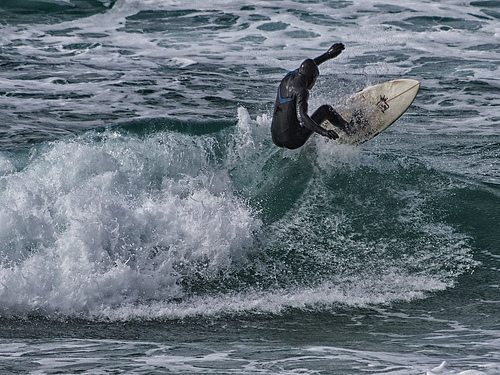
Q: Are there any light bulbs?
A: No, there are no light bulbs.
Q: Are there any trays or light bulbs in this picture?
A: No, there are no light bulbs or trays.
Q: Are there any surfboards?
A: Yes, there is a surfboard.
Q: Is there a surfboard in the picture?
A: Yes, there is a surfboard.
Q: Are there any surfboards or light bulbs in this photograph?
A: Yes, there is a surfboard.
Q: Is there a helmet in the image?
A: No, there are no helmets.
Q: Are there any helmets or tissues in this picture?
A: No, there are no helmets or tissues.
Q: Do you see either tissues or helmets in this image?
A: No, there are no helmets or tissues.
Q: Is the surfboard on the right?
A: Yes, the surfboard is on the right of the image.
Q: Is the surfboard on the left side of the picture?
A: No, the surfboard is on the right of the image.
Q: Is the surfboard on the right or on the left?
A: The surfboard is on the right of the image.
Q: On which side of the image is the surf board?
A: The surf board is on the right of the image.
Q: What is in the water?
A: The surfboard is in the water.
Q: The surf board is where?
A: The surf board is in the water.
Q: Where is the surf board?
A: The surf board is in the water.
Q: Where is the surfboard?
A: The surf board is in the water.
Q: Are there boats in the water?
A: No, there is a surfboard in the water.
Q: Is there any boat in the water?
A: No, there is a surfboard in the water.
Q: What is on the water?
A: The surf board is on the water.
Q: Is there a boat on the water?
A: No, there is a surfboard on the water.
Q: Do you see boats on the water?
A: No, there is a surfboard on the water.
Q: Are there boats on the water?
A: No, there is a surfboard on the water.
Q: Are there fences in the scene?
A: No, there are no fences.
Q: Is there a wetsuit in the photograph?
A: Yes, there is a wetsuit.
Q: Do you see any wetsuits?
A: Yes, there is a wetsuit.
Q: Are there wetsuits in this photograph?
A: Yes, there is a wetsuit.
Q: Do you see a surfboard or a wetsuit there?
A: Yes, there is a wetsuit.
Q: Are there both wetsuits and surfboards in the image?
A: Yes, there are both a wetsuit and a surfboard.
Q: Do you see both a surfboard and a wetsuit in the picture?
A: Yes, there are both a wetsuit and a surfboard.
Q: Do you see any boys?
A: No, there are no boys.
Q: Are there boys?
A: No, there are no boys.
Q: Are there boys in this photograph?
A: No, there are no boys.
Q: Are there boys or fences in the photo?
A: No, there are no boys or fences.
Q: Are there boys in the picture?
A: No, there are no boys.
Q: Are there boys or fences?
A: No, there are no boys or fences.